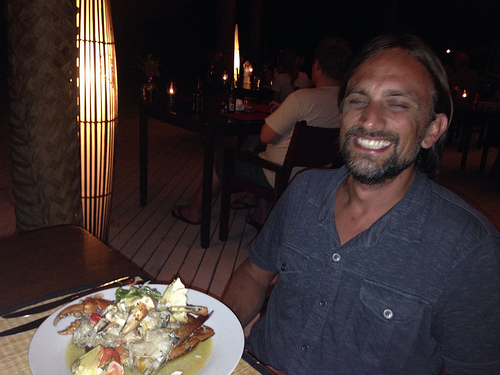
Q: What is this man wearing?
A: A blue shirt.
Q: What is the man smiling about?
A: The food.